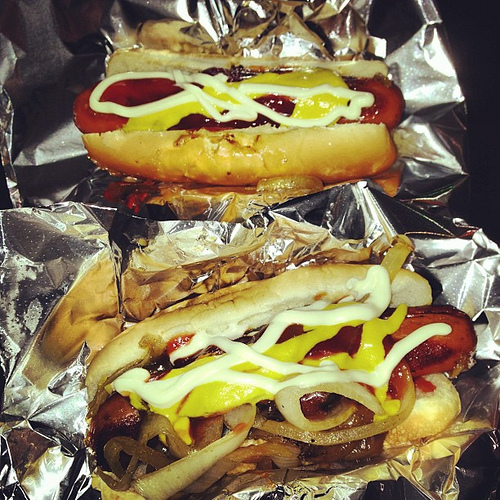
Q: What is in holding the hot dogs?
A: Aluminum foil.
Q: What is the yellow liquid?
A: Mustard.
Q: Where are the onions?
A: On a hotdog.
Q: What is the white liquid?
A: Mayonnaise.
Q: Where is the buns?
A: Holding the hotdogs.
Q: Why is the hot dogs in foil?
A: As a plate.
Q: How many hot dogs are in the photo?
A: 2.